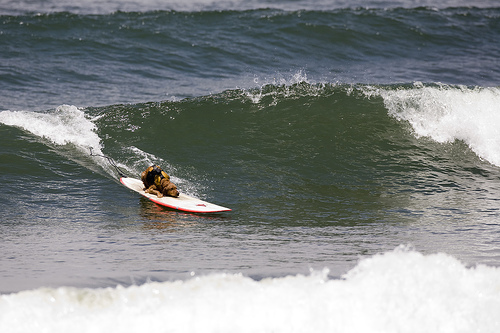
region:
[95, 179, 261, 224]
a white surfboard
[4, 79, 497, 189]
a large green wave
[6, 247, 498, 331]
a white splash in the forefront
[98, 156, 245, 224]
something riding a surfboard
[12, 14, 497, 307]
a scene outside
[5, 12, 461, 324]
a scene happening during the day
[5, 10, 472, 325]
scene at the beach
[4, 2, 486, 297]
large image of the ocean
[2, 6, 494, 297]
water is blue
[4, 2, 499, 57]
a small wave in the background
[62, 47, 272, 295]
a dog surfing in the water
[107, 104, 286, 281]
a dog wearing a life jacket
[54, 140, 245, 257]
a dog on a surfboard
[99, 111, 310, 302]
a dog laying on a surfboard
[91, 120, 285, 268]
a dog on the water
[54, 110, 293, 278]
a dog wearing a life jacket on a surfboard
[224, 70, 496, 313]
a body of water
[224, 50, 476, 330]
a body wavy water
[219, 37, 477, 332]
a body of water with waves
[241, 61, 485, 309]
waves in a body of water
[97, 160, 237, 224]
The dog is lying down.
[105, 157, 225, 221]
The dog is on a surfboard.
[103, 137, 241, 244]
The dog is brown.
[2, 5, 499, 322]
The waves are white.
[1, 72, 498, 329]
The waves are frothy.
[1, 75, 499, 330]
The water is foamy.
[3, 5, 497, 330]
The water is wavy.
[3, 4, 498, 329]
The water is zealous.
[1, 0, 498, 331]
The water is ripply.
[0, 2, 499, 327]
The water is engaging.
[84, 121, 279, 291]
a dog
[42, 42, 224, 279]
a dog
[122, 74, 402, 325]
a dog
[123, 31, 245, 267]
a dog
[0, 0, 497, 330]
A dog surfing in the ocean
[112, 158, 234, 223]
A dog on the surfboard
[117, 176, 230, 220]
A red and white surfboard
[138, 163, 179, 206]
A brown dog lying down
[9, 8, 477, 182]
The ocean is rough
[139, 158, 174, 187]
A yellow vest on the dog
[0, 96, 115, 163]
White seafoam on the wave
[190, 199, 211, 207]
A red logo on the surfboard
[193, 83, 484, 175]
A breaking wave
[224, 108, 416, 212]
Murky water by the surfboard